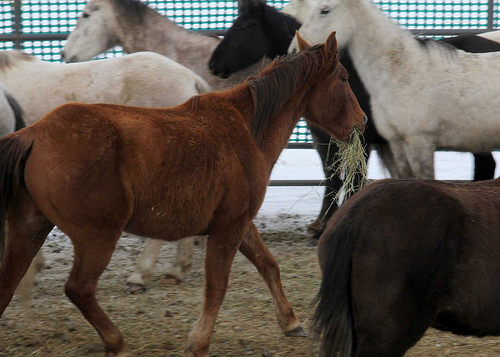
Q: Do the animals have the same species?
A: Yes, all the animals are horses.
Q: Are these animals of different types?
A: No, all the animals are horses.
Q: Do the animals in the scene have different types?
A: No, all the animals are horses.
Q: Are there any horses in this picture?
A: Yes, there is a horse.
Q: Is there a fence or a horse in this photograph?
A: Yes, there is a horse.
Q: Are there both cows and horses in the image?
A: No, there is a horse but no cows.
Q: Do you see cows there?
A: No, there are no cows.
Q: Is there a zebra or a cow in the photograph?
A: No, there are no cows or zebras.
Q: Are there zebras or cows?
A: No, there are no cows or zebras.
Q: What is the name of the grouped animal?
A: The animal is a horse.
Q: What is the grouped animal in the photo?
A: The animal is a horse.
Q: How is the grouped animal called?
A: The animal is a horse.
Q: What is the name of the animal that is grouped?
A: The animal is a horse.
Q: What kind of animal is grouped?
A: The animal is a horse.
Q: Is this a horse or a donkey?
A: This is a horse.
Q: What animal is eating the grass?
A: The horse is eating the grass.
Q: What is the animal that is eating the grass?
A: The animal is a horse.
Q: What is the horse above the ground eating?
A: The horse is eating grass.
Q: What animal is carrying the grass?
A: The horse is carrying the grass.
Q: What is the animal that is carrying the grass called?
A: The animal is a horse.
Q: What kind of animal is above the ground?
A: The animal is a horse.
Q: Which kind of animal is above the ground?
A: The animal is a horse.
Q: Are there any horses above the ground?
A: Yes, there is a horse above the ground.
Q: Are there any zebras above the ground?
A: No, there is a horse above the ground.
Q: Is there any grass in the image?
A: Yes, there is grass.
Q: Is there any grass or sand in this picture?
A: Yes, there is grass.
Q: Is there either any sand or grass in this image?
A: Yes, there is grass.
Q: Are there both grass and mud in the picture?
A: No, there is grass but no mud.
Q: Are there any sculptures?
A: No, there are no sculptures.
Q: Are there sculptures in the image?
A: No, there are no sculptures.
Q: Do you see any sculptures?
A: No, there are no sculptures.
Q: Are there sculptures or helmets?
A: No, there are no sculptures or helmets.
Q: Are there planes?
A: No, there are no planes.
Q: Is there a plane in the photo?
A: No, there are no airplanes.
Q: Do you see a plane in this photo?
A: No, there are no airplanes.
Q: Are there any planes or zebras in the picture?
A: No, there are no planes or zebras.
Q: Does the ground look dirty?
A: Yes, the ground is dirty.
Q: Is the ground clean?
A: No, the ground is dirty.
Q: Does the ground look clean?
A: No, the ground is dirty.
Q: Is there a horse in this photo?
A: Yes, there is a horse.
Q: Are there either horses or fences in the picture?
A: Yes, there is a horse.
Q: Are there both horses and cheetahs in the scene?
A: No, there is a horse but no cheetahs.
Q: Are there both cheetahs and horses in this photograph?
A: No, there is a horse but no cheetahs.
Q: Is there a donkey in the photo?
A: No, there are no donkeys.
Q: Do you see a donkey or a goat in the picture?
A: No, there are no donkeys or goats.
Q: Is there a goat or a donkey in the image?
A: No, there are no donkeys or goats.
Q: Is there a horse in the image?
A: Yes, there is a horse.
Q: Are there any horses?
A: Yes, there is a horse.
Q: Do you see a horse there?
A: Yes, there is a horse.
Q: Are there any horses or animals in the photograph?
A: Yes, there is a horse.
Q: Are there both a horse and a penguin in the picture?
A: No, there is a horse but no penguins.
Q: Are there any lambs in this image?
A: No, there are no lambs.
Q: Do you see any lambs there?
A: No, there are no lambs.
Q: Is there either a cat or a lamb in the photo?
A: No, there are no lambs or cats.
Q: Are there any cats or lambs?
A: No, there are no lambs or cats.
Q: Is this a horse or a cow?
A: This is a horse.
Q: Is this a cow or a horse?
A: This is a horse.